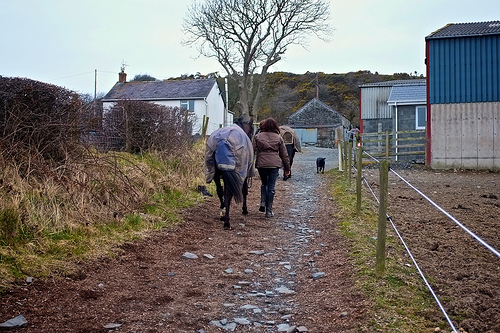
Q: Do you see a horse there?
A: Yes, there is a horse.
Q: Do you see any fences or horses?
A: Yes, there is a horse.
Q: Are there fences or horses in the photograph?
A: Yes, there is a horse.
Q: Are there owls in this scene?
A: No, there are no owls.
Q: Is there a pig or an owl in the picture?
A: No, there are no owls or pigs.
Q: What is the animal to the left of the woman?
A: The animal is a horse.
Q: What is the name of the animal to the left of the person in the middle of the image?
A: The animal is a horse.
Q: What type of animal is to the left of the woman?
A: The animal is a horse.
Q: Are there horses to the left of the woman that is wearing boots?
A: Yes, there is a horse to the left of the woman.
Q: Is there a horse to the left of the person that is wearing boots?
A: Yes, there is a horse to the left of the woman.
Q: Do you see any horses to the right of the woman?
A: No, the horse is to the left of the woman.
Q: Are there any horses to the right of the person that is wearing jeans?
A: No, the horse is to the left of the woman.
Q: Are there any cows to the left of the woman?
A: No, there is a horse to the left of the woman.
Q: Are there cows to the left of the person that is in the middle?
A: No, there is a horse to the left of the woman.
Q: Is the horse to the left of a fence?
A: No, the horse is to the left of a woman.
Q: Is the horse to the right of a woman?
A: No, the horse is to the left of a woman.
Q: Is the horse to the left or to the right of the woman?
A: The horse is to the left of the woman.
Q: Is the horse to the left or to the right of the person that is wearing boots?
A: The horse is to the left of the woman.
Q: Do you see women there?
A: Yes, there is a woman.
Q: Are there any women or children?
A: Yes, there is a woman.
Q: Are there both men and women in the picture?
A: No, there is a woman but no men.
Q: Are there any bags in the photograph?
A: No, there are no bags.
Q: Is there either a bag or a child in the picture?
A: No, there are no bags or children.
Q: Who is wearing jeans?
A: The woman is wearing jeans.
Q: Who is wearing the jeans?
A: The woman is wearing jeans.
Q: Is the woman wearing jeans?
A: Yes, the woman is wearing jeans.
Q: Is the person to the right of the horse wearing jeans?
A: Yes, the woman is wearing jeans.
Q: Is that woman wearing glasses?
A: No, the woman is wearing jeans.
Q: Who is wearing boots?
A: The woman is wearing boots.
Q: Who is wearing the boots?
A: The woman is wearing boots.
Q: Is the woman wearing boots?
A: Yes, the woman is wearing boots.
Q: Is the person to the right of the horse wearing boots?
A: Yes, the woman is wearing boots.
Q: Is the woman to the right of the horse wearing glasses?
A: No, the woman is wearing boots.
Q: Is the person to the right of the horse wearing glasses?
A: No, the woman is wearing boots.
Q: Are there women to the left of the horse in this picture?
A: No, the woman is to the right of the horse.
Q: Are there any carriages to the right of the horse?
A: No, there is a woman to the right of the horse.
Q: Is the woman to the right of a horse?
A: Yes, the woman is to the right of a horse.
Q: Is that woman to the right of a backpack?
A: No, the woman is to the right of a horse.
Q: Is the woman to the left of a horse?
A: No, the woman is to the right of a horse.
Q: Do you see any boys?
A: No, there are no boys.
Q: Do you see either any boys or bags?
A: No, there are no boys or bags.